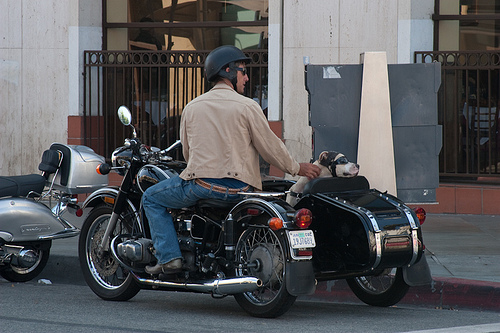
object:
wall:
[282, 0, 397, 180]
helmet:
[205, 46, 251, 92]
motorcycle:
[0, 143, 111, 284]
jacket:
[179, 85, 301, 192]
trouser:
[142, 175, 253, 265]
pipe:
[136, 276, 262, 294]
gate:
[83, 50, 268, 174]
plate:
[288, 229, 317, 249]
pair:
[226, 66, 251, 76]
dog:
[285, 151, 359, 207]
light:
[298, 250, 312, 257]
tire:
[76, 207, 143, 302]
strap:
[289, 191, 301, 198]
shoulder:
[231, 93, 254, 110]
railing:
[83, 41, 268, 171]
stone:
[282, 0, 339, 49]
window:
[105, 0, 269, 23]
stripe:
[67, 115, 81, 140]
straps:
[319, 151, 340, 167]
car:
[76, 105, 431, 318]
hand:
[297, 162, 321, 179]